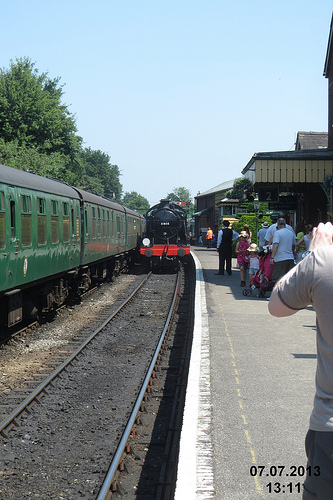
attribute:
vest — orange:
[206, 228, 213, 238]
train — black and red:
[139, 197, 189, 273]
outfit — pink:
[233, 236, 257, 255]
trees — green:
[3, 53, 153, 221]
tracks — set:
[1, 261, 186, 499]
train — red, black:
[137, 194, 193, 275]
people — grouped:
[209, 208, 294, 294]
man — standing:
[204, 225, 212, 248]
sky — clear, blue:
[131, 14, 238, 95]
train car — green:
[130, 200, 197, 268]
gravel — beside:
[1, 261, 144, 498]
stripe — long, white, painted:
[177, 251, 220, 494]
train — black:
[135, 197, 198, 279]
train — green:
[0, 174, 145, 341]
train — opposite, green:
[1, 161, 149, 345]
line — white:
[171, 243, 219, 497]